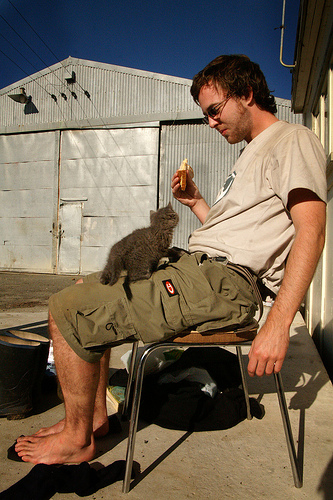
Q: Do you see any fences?
A: No, there are no fences.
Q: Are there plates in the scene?
A: No, there are no plates.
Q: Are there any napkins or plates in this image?
A: No, there are no plates or napkins.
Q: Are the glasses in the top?
A: Yes, the glasses are in the top of the image.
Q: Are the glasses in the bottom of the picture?
A: No, the glasses are in the top of the image.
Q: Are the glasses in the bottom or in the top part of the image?
A: The glasses are in the top of the image.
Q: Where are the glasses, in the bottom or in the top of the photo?
A: The glasses are in the top of the image.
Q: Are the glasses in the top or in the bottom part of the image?
A: The glasses are in the top of the image.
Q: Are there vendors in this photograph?
A: No, there are no vendors.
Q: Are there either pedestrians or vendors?
A: No, there are no vendors or pedestrians.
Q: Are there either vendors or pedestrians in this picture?
A: No, there are no vendors or pedestrians.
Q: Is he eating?
A: Yes, the man is eating.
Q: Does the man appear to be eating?
A: Yes, the man is eating.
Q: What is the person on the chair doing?
A: The man is eating.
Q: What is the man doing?
A: The man is eating.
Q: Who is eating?
A: The man is eating.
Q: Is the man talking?
A: No, the man is eating.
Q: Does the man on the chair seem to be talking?
A: No, the man is eating.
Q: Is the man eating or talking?
A: The man is eating.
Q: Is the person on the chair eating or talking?
A: The man is eating.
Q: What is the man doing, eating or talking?
A: The man is eating.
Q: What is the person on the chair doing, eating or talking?
A: The man is eating.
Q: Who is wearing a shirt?
A: The man is wearing a shirt.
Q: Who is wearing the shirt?
A: The man is wearing a shirt.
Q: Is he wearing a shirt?
A: Yes, the man is wearing a shirt.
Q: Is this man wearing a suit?
A: No, the man is wearing a shirt.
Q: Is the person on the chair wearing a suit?
A: No, the man is wearing a shirt.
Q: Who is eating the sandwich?
A: The man is eating the sandwich.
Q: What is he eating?
A: The man is eating a sandwich.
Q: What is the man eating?
A: The man is eating a sandwich.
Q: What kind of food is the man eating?
A: The man is eating a sandwich.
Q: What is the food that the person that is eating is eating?
A: The food is a sandwich.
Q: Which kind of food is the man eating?
A: The man is eating a sandwich.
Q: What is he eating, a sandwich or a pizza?
A: The man is eating a sandwich.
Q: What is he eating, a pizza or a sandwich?
A: The man is eating a sandwich.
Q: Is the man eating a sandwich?
A: Yes, the man is eating a sandwich.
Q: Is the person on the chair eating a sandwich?
A: Yes, the man is eating a sandwich.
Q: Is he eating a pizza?
A: No, the man is eating a sandwich.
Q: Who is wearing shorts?
A: The man is wearing shorts.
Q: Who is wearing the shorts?
A: The man is wearing shorts.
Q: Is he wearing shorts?
A: Yes, the man is wearing shorts.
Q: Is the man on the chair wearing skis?
A: No, the man is wearing shorts.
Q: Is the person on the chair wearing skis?
A: No, the man is wearing shorts.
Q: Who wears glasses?
A: The man wears glasses.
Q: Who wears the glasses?
A: The man wears glasses.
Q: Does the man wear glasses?
A: Yes, the man wears glasses.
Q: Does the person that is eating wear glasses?
A: Yes, the man wears glasses.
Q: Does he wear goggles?
A: No, the man wears glasses.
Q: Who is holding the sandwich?
A: The man is holding the sandwich.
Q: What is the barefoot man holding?
A: The man is holding the sandwich.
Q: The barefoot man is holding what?
A: The man is holding the sandwich.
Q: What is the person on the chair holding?
A: The man is holding the sandwich.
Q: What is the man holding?
A: The man is holding the sandwich.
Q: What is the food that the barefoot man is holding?
A: The food is a sandwich.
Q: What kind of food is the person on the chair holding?
A: The man is holding the sandwich.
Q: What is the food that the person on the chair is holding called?
A: The food is a sandwich.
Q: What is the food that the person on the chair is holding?
A: The food is a sandwich.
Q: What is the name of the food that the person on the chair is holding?
A: The food is a sandwich.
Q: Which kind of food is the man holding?
A: The man is holding the sandwich.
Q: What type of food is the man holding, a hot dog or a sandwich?
A: The man is holding a sandwich.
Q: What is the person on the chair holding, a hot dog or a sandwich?
A: The man is holding a sandwich.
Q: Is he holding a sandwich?
A: Yes, the man is holding a sandwich.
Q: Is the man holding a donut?
A: No, the man is holding a sandwich.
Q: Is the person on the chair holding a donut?
A: No, the man is holding a sandwich.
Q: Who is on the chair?
A: The man is on the chair.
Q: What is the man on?
A: The man is on the chair.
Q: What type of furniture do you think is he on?
A: The man is on the chair.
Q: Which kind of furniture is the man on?
A: The man is on the chair.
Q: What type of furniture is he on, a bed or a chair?
A: The man is on a chair.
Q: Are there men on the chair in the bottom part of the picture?
A: Yes, there is a man on the chair.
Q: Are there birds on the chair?
A: No, there is a man on the chair.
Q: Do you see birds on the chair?
A: No, there is a man on the chair.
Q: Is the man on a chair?
A: Yes, the man is on a chair.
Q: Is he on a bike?
A: No, the man is on a chair.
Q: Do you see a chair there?
A: Yes, there is a chair.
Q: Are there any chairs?
A: Yes, there is a chair.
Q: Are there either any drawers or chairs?
A: Yes, there is a chair.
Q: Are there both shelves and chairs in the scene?
A: No, there is a chair but no shelves.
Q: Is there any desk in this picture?
A: No, there are no desks.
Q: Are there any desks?
A: No, there are no desks.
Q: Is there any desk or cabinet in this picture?
A: No, there are no desks or cabinets.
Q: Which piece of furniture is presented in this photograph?
A: The piece of furniture is a chair.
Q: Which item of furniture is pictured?
A: The piece of furniture is a chair.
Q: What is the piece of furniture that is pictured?
A: The piece of furniture is a chair.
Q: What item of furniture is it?
A: The piece of furniture is a chair.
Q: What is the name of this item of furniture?
A: This is a chair.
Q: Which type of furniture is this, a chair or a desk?
A: This is a chair.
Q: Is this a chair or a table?
A: This is a chair.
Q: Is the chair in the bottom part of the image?
A: Yes, the chair is in the bottom of the image.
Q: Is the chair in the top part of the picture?
A: No, the chair is in the bottom of the image.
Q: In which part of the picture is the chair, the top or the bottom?
A: The chair is in the bottom of the image.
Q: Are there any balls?
A: No, there are no balls.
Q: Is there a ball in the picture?
A: No, there are no balls.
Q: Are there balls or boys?
A: No, there are no balls or boys.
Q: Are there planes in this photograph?
A: No, there are no planes.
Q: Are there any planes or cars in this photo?
A: No, there are no planes or cars.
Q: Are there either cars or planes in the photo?
A: No, there are no planes or cars.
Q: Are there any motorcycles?
A: No, there are no motorcycles.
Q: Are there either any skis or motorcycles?
A: No, there are no motorcycles or skis.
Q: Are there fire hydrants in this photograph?
A: No, there are no fire hydrants.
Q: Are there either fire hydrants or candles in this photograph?
A: No, there are no fire hydrants or candles.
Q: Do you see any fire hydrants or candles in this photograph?
A: No, there are no fire hydrants or candles.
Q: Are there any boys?
A: No, there are no boys.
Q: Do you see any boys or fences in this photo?
A: No, there are no boys or fences.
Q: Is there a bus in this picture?
A: No, there are no buses.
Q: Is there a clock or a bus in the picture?
A: No, there are no buses or clocks.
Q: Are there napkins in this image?
A: No, there are no napkins.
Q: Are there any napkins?
A: No, there are no napkins.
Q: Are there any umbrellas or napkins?
A: No, there are no napkins or umbrellas.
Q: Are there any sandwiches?
A: Yes, there is a sandwich.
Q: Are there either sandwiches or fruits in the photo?
A: Yes, there is a sandwich.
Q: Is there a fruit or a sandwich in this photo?
A: Yes, there is a sandwich.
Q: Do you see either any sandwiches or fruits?
A: Yes, there is a sandwich.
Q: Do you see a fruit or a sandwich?
A: Yes, there is a sandwich.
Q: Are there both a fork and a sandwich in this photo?
A: No, there is a sandwich but no forks.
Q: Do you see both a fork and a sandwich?
A: No, there is a sandwich but no forks.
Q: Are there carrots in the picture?
A: No, there are no carrots.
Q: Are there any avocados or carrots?
A: No, there are no carrots or avocados.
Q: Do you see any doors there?
A: Yes, there is a door.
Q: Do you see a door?
A: Yes, there is a door.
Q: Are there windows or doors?
A: Yes, there is a door.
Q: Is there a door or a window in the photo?
A: Yes, there is a door.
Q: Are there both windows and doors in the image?
A: No, there is a door but no windows.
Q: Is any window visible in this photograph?
A: No, there are no windows.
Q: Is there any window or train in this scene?
A: No, there are no windows or trains.